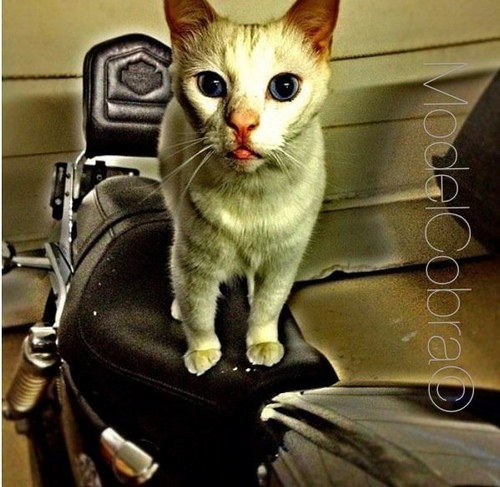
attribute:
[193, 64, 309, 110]
eyes — blue, large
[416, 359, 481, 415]
copyright symbol — here, white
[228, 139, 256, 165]
tongue — pink, sticking out, hanging out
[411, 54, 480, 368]
word — modelcobra, white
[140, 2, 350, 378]
cat — white, standing, sitting, orange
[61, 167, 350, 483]
seat — black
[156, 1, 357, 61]
ears — orange, pointy, pink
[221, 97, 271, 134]
nose — pink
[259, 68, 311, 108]
left eye — blue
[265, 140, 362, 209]
left side whiskers — white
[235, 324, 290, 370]
front left paw — here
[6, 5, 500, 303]
wall — white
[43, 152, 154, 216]
gas tank — black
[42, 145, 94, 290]
metal — silver